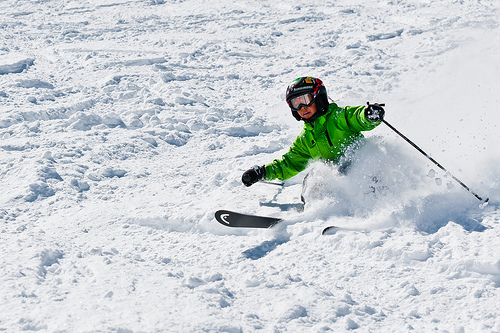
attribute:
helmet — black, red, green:
[278, 68, 335, 125]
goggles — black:
[285, 86, 316, 113]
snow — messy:
[30, 44, 201, 181]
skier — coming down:
[135, 30, 483, 228]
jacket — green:
[215, 62, 402, 193]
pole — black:
[364, 98, 499, 233]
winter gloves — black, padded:
[243, 135, 273, 225]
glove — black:
[240, 163, 268, 187]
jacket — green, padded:
[258, 99, 376, 214]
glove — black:
[369, 93, 386, 130]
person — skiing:
[236, 47, 441, 254]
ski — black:
[201, 183, 315, 244]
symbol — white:
[216, 208, 233, 225]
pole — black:
[365, 100, 488, 203]